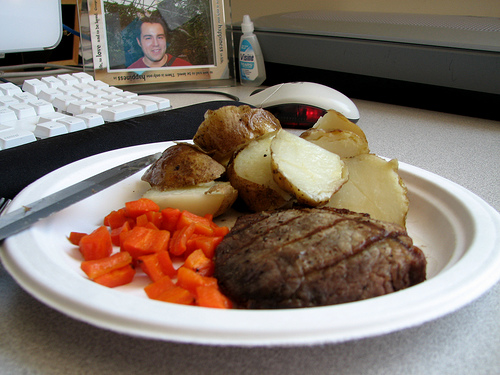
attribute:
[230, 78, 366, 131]
mouse — white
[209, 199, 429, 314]
meat — piece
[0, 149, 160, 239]
knife — stainless, steel, steak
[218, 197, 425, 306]
meat — cooked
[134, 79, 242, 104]
tail — black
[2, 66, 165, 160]
keyboard — computer, portion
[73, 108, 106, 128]
key — white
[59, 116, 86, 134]
key — white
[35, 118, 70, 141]
key — white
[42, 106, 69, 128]
key — white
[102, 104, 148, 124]
key — white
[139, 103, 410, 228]
potato — cut, baked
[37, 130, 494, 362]
plate — white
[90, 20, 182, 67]
photo — man's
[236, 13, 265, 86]
bottle — plastic 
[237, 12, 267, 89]
bottle — eyedrops, Visine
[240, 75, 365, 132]
mouse — white, computer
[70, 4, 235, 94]
frame — metal, with engraving